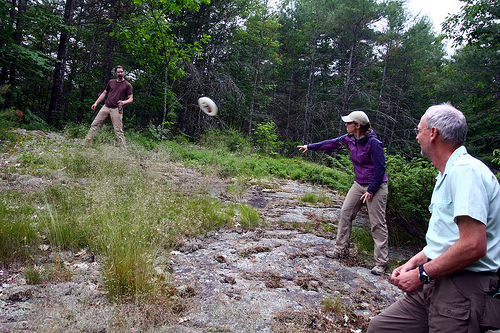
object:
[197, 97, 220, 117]
frisbee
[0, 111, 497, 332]
grass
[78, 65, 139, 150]
man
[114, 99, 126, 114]
bottle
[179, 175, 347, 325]
air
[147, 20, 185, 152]
tree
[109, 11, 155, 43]
leaves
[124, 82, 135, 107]
arm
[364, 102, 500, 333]
man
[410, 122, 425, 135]
glasses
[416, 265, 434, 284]
watch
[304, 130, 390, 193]
jacket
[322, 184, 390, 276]
pants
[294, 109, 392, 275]
woman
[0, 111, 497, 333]
area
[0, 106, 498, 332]
plants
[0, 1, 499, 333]
background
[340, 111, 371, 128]
cap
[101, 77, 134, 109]
shirt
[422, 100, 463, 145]
hair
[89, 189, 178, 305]
weeds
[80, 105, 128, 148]
pants